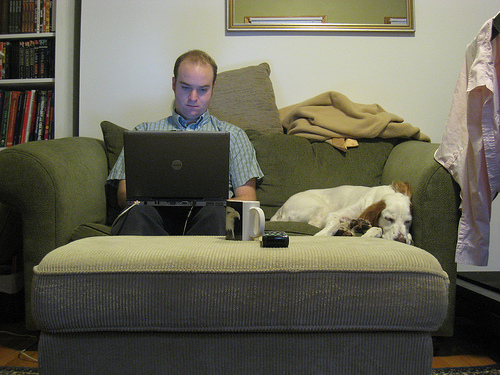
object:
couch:
[1, 110, 464, 356]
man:
[104, 49, 267, 238]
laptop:
[122, 138, 232, 216]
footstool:
[24, 234, 452, 374]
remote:
[259, 230, 290, 248]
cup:
[225, 198, 265, 240]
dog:
[270, 184, 413, 246]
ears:
[358, 200, 386, 227]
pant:
[133, 239, 251, 274]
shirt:
[103, 107, 266, 204]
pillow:
[207, 61, 286, 136]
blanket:
[276, 92, 431, 154]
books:
[45, 37, 57, 79]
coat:
[55, 0, 82, 139]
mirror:
[224, 14, 416, 33]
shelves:
[0, 0, 59, 163]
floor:
[56, 318, 92, 334]